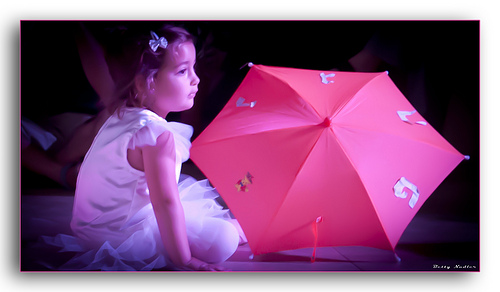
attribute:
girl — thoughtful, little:
[77, 26, 202, 267]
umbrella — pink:
[192, 61, 464, 254]